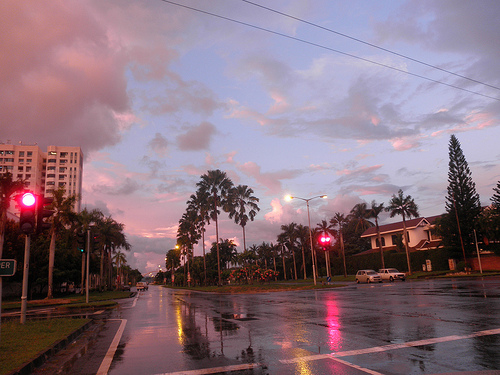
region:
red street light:
[17, 189, 61, 255]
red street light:
[315, 232, 344, 258]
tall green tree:
[436, 139, 471, 230]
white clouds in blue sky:
[12, 10, 93, 57]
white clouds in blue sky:
[18, 59, 119, 106]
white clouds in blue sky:
[90, 34, 144, 99]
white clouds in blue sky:
[107, 78, 187, 148]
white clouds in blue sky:
[106, 127, 151, 185]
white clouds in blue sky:
[209, 28, 295, 112]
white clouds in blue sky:
[295, 71, 353, 144]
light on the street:
[315, 292, 345, 345]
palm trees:
[172, 205, 252, 230]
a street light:
[17, 191, 39, 229]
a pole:
[19, 235, 38, 327]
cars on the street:
[350, 265, 407, 287]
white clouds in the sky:
[30, 23, 177, 139]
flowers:
[245, 262, 277, 285]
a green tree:
[438, 143, 483, 222]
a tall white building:
[0, 144, 83, 179]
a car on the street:
[131, 272, 158, 294]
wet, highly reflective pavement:
[3, 273, 499, 373]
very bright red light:
[316, 228, 335, 247]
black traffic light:
[7, 185, 56, 242]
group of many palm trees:
[163, 166, 421, 287]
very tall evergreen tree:
[438, 130, 490, 270]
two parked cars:
[354, 267, 405, 286]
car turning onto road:
[133, 280, 149, 292]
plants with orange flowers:
[216, 264, 283, 284]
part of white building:
[0, 135, 84, 215]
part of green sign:
[2, 259, 17, 279]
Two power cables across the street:
[320, 24, 325, 48]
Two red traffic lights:
[319, 235, 331, 243]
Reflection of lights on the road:
[325, 300, 339, 336]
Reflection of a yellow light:
[173, 310, 183, 340]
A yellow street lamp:
[173, 243, 181, 251]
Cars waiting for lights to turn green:
[353, 266, 406, 282]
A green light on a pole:
[78, 248, 88, 253]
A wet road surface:
[142, 324, 171, 366]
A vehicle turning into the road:
[135, 279, 147, 291]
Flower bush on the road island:
[252, 270, 266, 277]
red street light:
[6, 184, 51, 224]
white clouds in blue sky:
[100, 67, 183, 120]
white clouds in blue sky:
[146, 34, 205, 85]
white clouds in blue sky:
[168, 69, 260, 130]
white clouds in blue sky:
[274, 31, 377, 108]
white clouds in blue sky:
[275, 122, 375, 199]